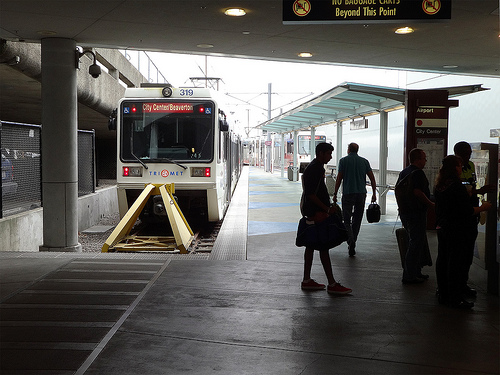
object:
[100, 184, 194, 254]
yellow triangle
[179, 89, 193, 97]
number 319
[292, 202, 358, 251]
duffel bag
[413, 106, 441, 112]
white letters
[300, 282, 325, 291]
red sneakers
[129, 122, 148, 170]
windshield wipers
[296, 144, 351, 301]
guy in red sneaker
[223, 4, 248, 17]
illuminated lights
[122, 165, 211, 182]
set of two lights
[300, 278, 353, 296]
wearing red shoes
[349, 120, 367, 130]
sign hanging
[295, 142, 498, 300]
several people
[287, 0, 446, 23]
sign warning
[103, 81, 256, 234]
passenger train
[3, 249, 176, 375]
crosswalk lines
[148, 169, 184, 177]
number written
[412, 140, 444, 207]
train time schedule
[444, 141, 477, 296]
train worker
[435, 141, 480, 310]
people at a station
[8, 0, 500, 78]
roof has lights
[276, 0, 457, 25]
ceiling has a sign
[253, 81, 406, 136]
roof is green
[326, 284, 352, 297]
tennis shoes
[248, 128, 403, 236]
lines on the concre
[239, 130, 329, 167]
car behind a fence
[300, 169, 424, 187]
black fence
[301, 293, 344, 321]
two legs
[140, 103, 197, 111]
white lettered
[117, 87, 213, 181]
front of train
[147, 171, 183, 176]
tri met sign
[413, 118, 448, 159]
city center sign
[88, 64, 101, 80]
camera suspended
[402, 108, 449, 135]
airport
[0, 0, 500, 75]
ceiling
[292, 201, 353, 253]
luggage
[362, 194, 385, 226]
bag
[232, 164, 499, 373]
platform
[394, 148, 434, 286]
man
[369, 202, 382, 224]
luggage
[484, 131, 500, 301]
riders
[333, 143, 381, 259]
man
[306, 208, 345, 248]
bags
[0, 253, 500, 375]
concrete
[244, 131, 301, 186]
fence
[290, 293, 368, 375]
shadow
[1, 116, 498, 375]
airport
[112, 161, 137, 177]
lights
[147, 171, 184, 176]
blue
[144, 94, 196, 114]
letters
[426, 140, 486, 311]
two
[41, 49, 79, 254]
column